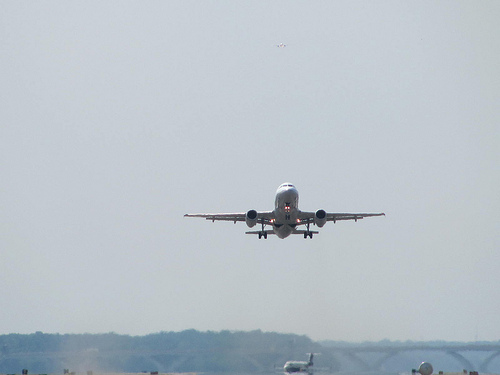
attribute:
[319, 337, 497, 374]
bridge — distant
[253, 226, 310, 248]
wheels — round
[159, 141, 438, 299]
airplane — jet